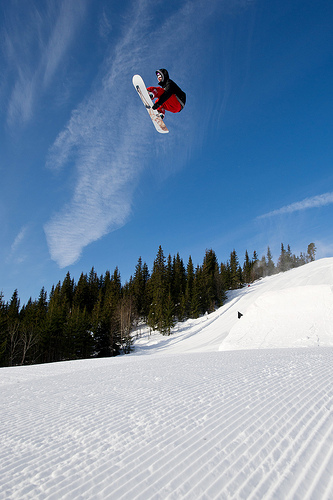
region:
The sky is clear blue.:
[5, 34, 318, 254]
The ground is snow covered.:
[45, 262, 324, 474]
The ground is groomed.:
[11, 350, 325, 496]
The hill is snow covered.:
[219, 247, 327, 359]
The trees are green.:
[2, 234, 310, 361]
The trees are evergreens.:
[26, 243, 294, 340]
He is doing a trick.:
[112, 48, 190, 133]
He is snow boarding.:
[113, 66, 202, 144]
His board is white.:
[123, 74, 170, 149]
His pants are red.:
[137, 89, 182, 118]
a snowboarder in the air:
[121, 42, 215, 166]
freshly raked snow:
[1, 357, 331, 499]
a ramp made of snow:
[225, 285, 332, 351]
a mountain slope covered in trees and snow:
[1, 245, 329, 499]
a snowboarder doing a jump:
[117, 48, 232, 152]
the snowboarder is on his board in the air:
[123, 50, 212, 143]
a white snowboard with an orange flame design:
[130, 72, 175, 144]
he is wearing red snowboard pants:
[144, 82, 180, 120]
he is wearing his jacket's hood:
[151, 61, 190, 115]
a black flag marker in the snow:
[234, 308, 245, 323]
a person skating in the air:
[132, 69, 192, 135]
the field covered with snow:
[3, 370, 324, 497]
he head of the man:
[155, 67, 169, 81]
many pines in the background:
[0, 249, 237, 348]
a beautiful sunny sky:
[107, 134, 322, 249]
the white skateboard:
[131, 76, 168, 137]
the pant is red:
[150, 85, 182, 116]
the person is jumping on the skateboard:
[126, 68, 187, 133]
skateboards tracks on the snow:
[61, 391, 319, 492]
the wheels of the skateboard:
[133, 85, 152, 115]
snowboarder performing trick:
[132, 59, 184, 137]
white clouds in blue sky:
[9, 18, 55, 67]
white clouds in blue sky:
[19, 66, 67, 111]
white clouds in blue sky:
[29, 128, 69, 172]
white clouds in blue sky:
[22, 146, 51, 201]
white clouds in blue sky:
[68, 184, 119, 236]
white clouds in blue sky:
[131, 190, 206, 229]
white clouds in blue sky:
[210, 125, 238, 174]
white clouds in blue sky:
[253, 160, 303, 213]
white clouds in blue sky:
[127, 24, 176, 54]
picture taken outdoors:
[9, 32, 332, 401]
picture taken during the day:
[21, 51, 110, 207]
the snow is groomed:
[82, 377, 217, 451]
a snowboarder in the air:
[120, 55, 202, 146]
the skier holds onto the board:
[154, 96, 165, 113]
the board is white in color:
[136, 70, 158, 130]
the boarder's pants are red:
[151, 87, 167, 96]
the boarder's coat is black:
[162, 79, 179, 92]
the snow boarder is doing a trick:
[116, 45, 202, 153]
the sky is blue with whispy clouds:
[75, 61, 104, 165]